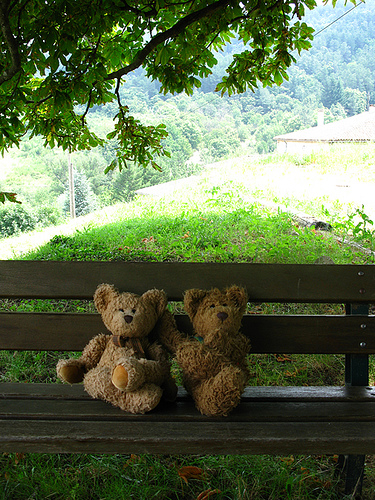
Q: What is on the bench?
A: Teddy bears.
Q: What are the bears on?
A: Bench.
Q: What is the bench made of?
A: Wood.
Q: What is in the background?
A: Trees.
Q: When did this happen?
A: During the day time.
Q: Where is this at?
A: A meadow.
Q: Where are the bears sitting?
A: On a bench.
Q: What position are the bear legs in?
A: Crossed.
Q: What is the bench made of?
A: Wood.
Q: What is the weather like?
A: Sunny.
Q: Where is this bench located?
A: In a park.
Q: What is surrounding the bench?
A: Grass and trees.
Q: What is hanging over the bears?
A: A tree limb.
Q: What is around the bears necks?
A: Bow ties.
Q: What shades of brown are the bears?
A: One is light and the other dark.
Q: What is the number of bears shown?
A: 2.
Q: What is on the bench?
A: Teddy bears.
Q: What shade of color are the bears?
A: Brown.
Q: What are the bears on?
A: Bench.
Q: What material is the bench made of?
A: Wood.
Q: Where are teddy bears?
A: On a bench.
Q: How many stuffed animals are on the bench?
A: Two.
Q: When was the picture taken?
A: Daytime.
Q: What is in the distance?
A: Trees.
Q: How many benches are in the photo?
A: One.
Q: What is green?
A: Grass.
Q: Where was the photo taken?
A: In a park.